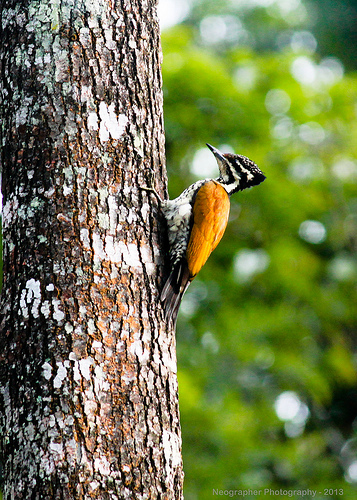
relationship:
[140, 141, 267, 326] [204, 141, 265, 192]
bird has head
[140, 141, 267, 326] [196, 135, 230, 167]
bird has beak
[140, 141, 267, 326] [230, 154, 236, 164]
bird has eye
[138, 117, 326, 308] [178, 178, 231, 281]
bird has wing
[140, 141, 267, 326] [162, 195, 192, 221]
bird has feathers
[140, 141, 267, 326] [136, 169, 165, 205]
bird has leg